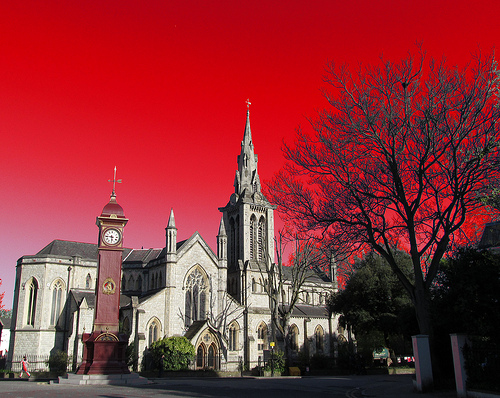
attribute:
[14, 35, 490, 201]
sky — red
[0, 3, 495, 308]
sky — red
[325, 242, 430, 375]
tree — large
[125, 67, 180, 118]
clouds — white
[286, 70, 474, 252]
tree — bare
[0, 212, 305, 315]
clouds — white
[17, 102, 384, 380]
church — large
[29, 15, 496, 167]
sky — red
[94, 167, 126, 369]
tower — red, clock tower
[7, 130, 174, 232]
clouds — white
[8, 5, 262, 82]
sky — red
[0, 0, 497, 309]
clouds — white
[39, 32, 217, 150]
sky — red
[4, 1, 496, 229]
sky — red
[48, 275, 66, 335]
tall window — very tall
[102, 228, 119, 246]
clock — white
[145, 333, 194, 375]
bushes — large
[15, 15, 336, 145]
sky — red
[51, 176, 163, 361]
tower — tall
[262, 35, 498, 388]
large tree — very large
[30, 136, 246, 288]
clouds — white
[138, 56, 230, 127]
clouds — white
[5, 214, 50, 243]
clouds — white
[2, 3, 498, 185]
sky — red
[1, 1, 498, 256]
sky — red, fading to pink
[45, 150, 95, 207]
clouds — white